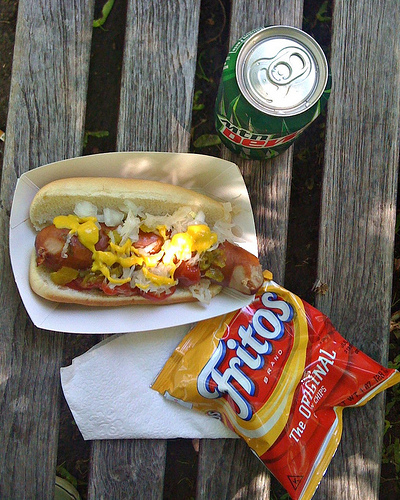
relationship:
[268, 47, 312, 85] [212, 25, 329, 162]
tab on can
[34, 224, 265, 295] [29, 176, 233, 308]
hotdog in bun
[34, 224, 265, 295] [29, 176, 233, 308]
hotdog on bun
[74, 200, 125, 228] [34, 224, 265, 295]
onions on hotdog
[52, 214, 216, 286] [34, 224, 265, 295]
mustard on hotdog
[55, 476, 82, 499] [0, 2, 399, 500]
shoe under bench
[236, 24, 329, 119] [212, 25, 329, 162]
top of can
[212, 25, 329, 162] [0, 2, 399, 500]
can on bench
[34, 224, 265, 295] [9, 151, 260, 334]
hotdog in container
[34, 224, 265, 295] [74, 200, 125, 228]
hotdog has onions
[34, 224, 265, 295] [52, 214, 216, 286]
hotdog has mustard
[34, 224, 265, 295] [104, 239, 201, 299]
hotdog has ketchup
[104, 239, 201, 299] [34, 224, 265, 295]
ketchup on hotdog